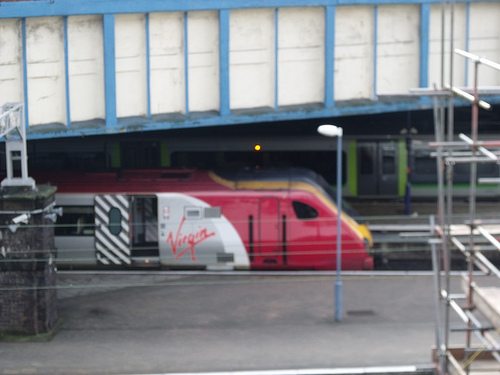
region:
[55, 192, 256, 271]
silver train on the train tracks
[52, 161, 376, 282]
red and yellow train on the train tracks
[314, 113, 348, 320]
silver pole with white lamp on platform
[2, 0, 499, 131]
blue and white overpass over trains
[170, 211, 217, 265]
red "Virgin" logo on side of train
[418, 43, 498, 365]
silver metal scaffolding on right side of platform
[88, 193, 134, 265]
black and white striped door of train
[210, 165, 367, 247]
yellow stripe across top and front of train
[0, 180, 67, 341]
red brick post on grey concrete platform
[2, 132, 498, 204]
green and silver train under overpass behind red train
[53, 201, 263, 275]
white train car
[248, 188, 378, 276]
pink and yellow front of car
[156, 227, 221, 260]
name of company on side of car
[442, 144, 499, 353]
silver poles near platform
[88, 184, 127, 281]
striped door on car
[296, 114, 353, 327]
long lighted post with light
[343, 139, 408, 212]
two gray doors on train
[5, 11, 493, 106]
wall of tunnel is blue and white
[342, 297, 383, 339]
vent in the ground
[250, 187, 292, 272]
pink door on the train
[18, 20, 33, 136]
blue beam on bridge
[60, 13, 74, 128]
blue beam on bridge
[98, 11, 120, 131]
blue beam on bridge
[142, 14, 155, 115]
blue beam on bridge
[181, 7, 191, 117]
blue beam on bridge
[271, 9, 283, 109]
blue beam on bridge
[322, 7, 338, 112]
blue beam on bridge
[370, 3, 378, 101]
blue beam on bridge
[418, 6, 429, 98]
blue beam on bridge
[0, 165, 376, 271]
a train is traveling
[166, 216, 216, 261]
virgin written on train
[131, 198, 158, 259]
the door is open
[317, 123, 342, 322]
grey and white light pole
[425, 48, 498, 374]
scaffold near the camera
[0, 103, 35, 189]
an overhanging metal object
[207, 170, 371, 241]
stripe of yellow paint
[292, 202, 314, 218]
a small black window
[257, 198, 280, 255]
the door is closed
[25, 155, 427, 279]
train on the tracks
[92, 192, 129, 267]
black and white stripes on the train door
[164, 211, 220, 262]
red Virgin logo on the side of the train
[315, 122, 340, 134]
light on the top of the pole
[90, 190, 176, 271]
door is open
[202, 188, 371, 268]
red paint on the side of the train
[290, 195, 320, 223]
small window on the front of the train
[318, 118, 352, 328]
light on top of the blue pole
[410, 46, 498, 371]
metal structure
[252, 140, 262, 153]
small yellow dot